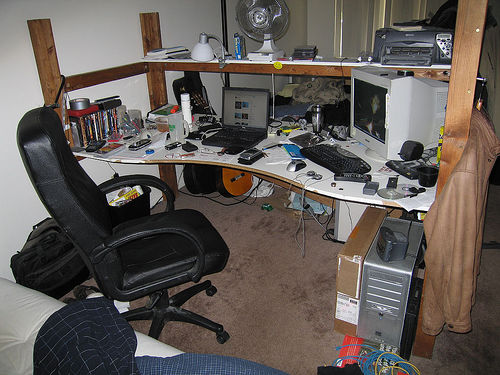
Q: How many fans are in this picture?
A: One.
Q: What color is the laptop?
A: Black.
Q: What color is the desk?
A: White and brown.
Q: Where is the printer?
A: On the desk shelf.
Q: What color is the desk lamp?
A: White.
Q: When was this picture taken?
A: During the day.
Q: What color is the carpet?
A: Brown.